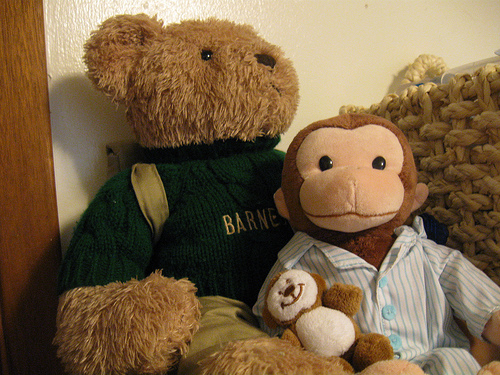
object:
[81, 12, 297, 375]
toy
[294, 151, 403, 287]
toy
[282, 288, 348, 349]
toy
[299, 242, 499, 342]
pajamas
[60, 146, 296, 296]
sweater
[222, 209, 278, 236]
embroidery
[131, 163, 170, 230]
overalls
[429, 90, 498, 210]
basket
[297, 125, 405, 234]
face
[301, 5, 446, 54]
wall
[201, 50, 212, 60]
eye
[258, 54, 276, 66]
nose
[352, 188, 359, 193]
nose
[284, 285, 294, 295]
nose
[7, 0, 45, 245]
door frame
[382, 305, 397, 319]
button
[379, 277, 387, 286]
button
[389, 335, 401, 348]
button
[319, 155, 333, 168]
eye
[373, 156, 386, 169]
eye